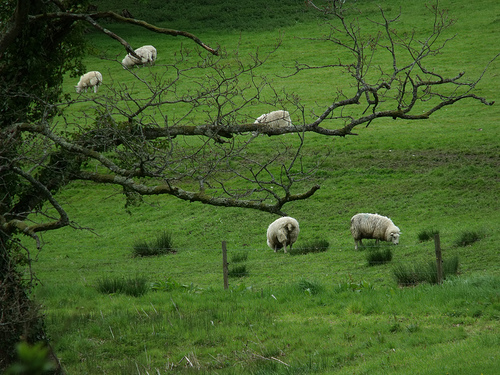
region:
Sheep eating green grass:
[338, 201, 405, 258]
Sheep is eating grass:
[252, 209, 309, 261]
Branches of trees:
[67, 19, 494, 229]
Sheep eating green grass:
[67, 55, 114, 106]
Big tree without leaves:
[3, 1, 71, 365]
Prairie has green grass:
[57, 10, 497, 371]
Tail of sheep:
[285, 220, 295, 232]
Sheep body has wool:
[347, 211, 394, 241]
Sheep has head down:
[116, 42, 165, 73]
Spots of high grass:
[85, 258, 153, 308]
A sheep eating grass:
[350, 198, 433, 261]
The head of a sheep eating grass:
[388, 220, 408, 249]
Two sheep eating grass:
[219, 209, 422, 265]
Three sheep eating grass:
[213, 105, 428, 292]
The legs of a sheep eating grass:
[350, 235, 370, 250]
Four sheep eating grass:
[117, 44, 428, 260]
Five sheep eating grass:
[66, 53, 433, 262]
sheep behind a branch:
[234, 105, 313, 143]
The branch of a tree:
[315, 40, 473, 147]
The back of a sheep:
[244, 209, 322, 269]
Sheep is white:
[340, 195, 412, 265]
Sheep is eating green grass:
[250, 205, 307, 256]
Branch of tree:
[70, 35, 465, 191]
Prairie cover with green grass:
[25, 15, 495, 370]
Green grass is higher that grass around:
[121, 220, 186, 266]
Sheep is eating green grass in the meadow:
[115, 35, 162, 75]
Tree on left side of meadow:
[1, 12, 71, 368]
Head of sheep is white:
[384, 224, 404, 251]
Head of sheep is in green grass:
[68, 59, 114, 99]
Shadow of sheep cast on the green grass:
[303, 234, 343, 265]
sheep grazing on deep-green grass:
[60, 32, 440, 279]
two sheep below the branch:
[110, 180, 435, 291]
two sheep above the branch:
[70, 40, 175, 145]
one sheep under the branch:
[216, 102, 318, 142]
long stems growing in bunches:
[87, 220, 207, 306]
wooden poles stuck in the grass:
[201, 220, 462, 305]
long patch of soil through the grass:
[200, 135, 486, 185]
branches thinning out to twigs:
[16, 86, 242, 221]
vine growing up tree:
[5, 20, 160, 360]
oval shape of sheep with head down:
[255, 210, 305, 256]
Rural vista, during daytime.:
[10, 5, 498, 369]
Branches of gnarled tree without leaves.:
[6, 17, 481, 211]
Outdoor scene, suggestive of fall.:
[8, 9, 496, 365]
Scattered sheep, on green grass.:
[72, 47, 444, 330]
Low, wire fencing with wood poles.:
[111, 233, 496, 290]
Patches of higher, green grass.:
[88, 236, 193, 309]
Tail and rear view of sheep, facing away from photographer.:
[267, 219, 321, 274]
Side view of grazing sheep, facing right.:
[346, 205, 421, 252]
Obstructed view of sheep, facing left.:
[255, 107, 305, 142]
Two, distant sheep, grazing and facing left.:
[73, 38, 178, 103]